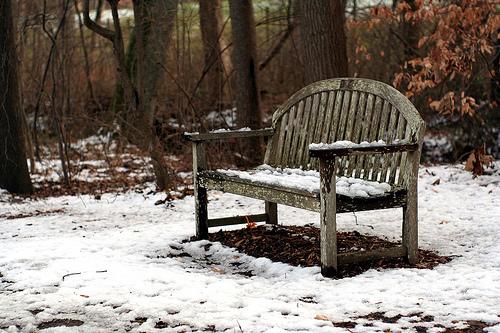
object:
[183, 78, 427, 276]
bench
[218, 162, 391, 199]
snow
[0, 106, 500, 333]
ground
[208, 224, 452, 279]
leaves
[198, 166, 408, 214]
seat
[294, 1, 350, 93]
tree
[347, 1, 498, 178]
leaves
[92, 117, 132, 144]
branch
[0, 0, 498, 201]
bush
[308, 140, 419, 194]
arm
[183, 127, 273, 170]
arm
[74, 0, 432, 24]
stream